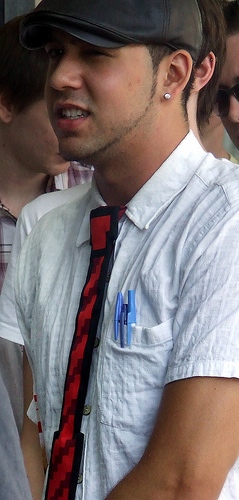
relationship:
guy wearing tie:
[15, 0, 239, 500] [42, 200, 120, 498]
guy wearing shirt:
[15, 0, 239, 500] [0, 132, 233, 498]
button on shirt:
[80, 402, 95, 421] [0, 132, 233, 498]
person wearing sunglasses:
[212, 0, 239, 152] [211, 81, 238, 116]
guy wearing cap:
[15, 0, 239, 500] [18, 0, 203, 52]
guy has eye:
[15, 0, 239, 500] [48, 39, 66, 57]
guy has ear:
[15, 0, 239, 500] [161, 48, 193, 102]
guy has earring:
[1, 13, 219, 268] [155, 81, 178, 104]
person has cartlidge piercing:
[185, 0, 238, 153] [209, 54, 217, 64]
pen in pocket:
[127, 289, 136, 345] [97, 316, 173, 435]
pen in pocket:
[119, 304, 126, 348] [97, 316, 173, 435]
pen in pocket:
[113, 292, 122, 340] [97, 316, 173, 435]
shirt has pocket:
[0, 132, 233, 498] [97, 316, 173, 435]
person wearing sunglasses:
[215, 56, 237, 143] [210, 77, 236, 110]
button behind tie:
[105, 271, 110, 282] [41, 195, 135, 499]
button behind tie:
[92, 336, 99, 349] [41, 195, 135, 499]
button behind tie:
[81, 403, 91, 414] [41, 195, 135, 499]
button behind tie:
[76, 473, 83, 485] [41, 195, 135, 499]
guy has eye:
[15, 0, 239, 500] [81, 48, 113, 59]